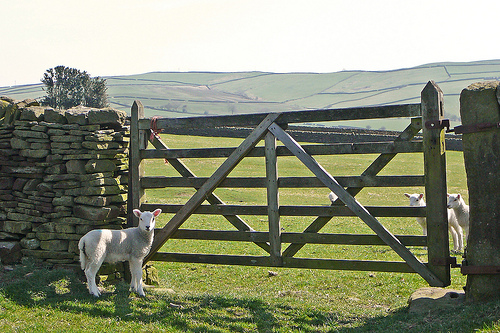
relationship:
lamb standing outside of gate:
[78, 209, 162, 299] [131, 81, 451, 287]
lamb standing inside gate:
[445, 192, 470, 253] [131, 81, 451, 287]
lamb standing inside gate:
[403, 192, 464, 253] [131, 81, 451, 287]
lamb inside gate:
[445, 192, 470, 253] [131, 81, 451, 287]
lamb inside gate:
[403, 192, 464, 253] [131, 81, 451, 287]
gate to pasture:
[131, 81, 451, 287] [130, 118, 470, 293]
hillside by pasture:
[0, 59, 499, 134] [130, 118, 470, 293]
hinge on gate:
[425, 119, 498, 133] [131, 81, 451, 287]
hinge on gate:
[435, 258, 500, 274] [131, 81, 451, 287]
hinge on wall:
[425, 119, 498, 133] [459, 81, 499, 304]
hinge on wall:
[435, 258, 500, 274] [459, 81, 499, 304]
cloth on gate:
[149, 117, 164, 141] [131, 81, 451, 287]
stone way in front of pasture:
[0, 79, 499, 302] [130, 118, 470, 293]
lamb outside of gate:
[78, 209, 162, 299] [131, 81, 451, 287]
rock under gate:
[407, 285, 467, 320] [131, 81, 451, 287]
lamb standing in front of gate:
[78, 209, 162, 299] [131, 81, 451, 287]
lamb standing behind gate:
[445, 192, 470, 253] [131, 81, 451, 287]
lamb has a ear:
[78, 209, 162, 299] [152, 208, 161, 216]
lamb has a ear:
[78, 209, 162, 299] [131, 209, 142, 217]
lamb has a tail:
[78, 209, 162, 299] [78, 239, 87, 270]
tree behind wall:
[39, 66, 112, 109] [0, 99, 130, 270]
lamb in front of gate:
[78, 209, 162, 299] [131, 81, 451, 287]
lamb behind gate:
[445, 192, 470, 253] [131, 81, 451, 287]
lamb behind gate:
[403, 192, 464, 253] [131, 81, 451, 287]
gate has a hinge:
[131, 81, 451, 287] [425, 119, 498, 133]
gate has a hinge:
[131, 81, 451, 287] [435, 258, 500, 274]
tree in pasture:
[39, 66, 112, 109] [130, 118, 470, 293]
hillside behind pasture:
[0, 59, 499, 134] [130, 118, 470, 293]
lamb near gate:
[78, 209, 162, 299] [131, 81, 451, 287]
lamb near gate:
[445, 192, 470, 253] [131, 81, 451, 287]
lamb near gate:
[403, 192, 464, 253] [131, 81, 451, 287]